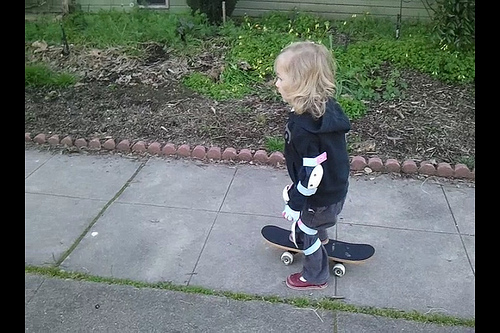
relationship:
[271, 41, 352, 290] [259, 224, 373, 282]
girl on skateboard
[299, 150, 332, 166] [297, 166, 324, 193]
strap on elbow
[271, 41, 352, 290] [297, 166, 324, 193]
girl has elbow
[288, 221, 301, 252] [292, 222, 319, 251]
knee pad over knee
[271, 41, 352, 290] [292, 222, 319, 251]
girl has knee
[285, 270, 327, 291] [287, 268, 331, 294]
shoe on foot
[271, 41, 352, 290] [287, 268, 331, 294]
girl has foot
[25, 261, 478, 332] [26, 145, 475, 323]
grass growing along edge sidewalk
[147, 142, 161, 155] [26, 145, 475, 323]
landscaping brick along edge of sidewalk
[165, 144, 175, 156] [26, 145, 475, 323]
landscaping brick along edge of sidewalk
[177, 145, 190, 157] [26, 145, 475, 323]
landscaping brick along edge of sidewalk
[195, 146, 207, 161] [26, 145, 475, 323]
landscaping brick along edge of sidewalk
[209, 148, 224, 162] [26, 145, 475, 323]
landscaping brick along edge of sidewalk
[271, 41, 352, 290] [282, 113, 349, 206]
girl wearing jacket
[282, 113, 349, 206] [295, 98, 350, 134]
jacket has hood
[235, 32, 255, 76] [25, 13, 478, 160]
flower growing in yard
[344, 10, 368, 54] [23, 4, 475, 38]
flower next to house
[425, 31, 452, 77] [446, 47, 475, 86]
flower next to flower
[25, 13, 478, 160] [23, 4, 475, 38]
yard on side of house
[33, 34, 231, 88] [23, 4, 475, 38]
clump of leaves on side of house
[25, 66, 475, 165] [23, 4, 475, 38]
dirt on side of house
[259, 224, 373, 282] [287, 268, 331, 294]
skateboard under foot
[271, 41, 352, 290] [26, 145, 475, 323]
girl skating on sidewalk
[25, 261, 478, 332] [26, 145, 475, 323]
grass growing between sidewalk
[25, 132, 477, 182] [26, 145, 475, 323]
brick trim on sidewalk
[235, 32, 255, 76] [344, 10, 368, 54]
flower next to flower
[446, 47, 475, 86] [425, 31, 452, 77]
flower next to flower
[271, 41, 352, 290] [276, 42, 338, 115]
girl has hair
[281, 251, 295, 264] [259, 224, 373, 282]
front wheel of skateboard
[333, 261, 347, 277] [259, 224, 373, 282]
back wheel of skateboard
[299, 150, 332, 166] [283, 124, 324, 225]
strap on arm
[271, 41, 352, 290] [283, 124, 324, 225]
girl has arm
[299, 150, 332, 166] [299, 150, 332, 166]
strap has strap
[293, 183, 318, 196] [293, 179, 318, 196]
strap has strap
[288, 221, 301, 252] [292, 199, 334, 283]
knee pad on left leg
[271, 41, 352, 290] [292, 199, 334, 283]
girl has left leg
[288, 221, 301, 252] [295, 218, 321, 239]
knee pad has strap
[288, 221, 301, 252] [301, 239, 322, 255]
knee pad has strap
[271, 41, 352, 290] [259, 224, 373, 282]
girl riding skateboard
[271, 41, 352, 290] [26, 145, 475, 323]
girl riding on sidewalk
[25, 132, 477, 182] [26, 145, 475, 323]
brick trim edged on sidewalk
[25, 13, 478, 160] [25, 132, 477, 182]
yard edged by brick trim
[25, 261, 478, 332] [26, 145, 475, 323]
grass on sidewalk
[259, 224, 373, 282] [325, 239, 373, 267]
skateboard has back part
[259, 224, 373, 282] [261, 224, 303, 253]
skateboard has front part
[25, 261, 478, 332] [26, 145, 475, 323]
grass along sidewalk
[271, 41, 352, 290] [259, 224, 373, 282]
girl trying to ride skateboard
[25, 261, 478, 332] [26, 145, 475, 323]
grass growing in sidewalk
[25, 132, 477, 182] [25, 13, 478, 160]
brick trim borders yard